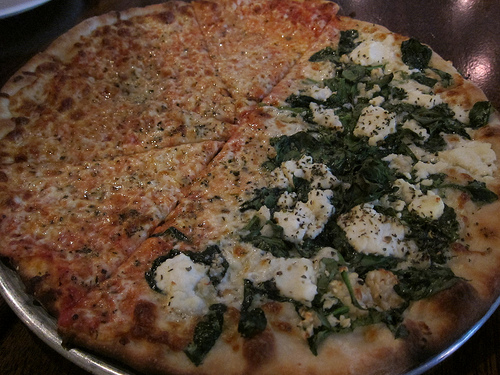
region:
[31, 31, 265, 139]
a piece of food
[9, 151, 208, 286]
a piece of food item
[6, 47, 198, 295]
a piece of pizza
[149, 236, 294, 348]
a decoration on food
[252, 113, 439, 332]
a decoration on food item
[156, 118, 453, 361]
a decoration on pizza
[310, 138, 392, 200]
green leaves on the food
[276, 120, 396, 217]
green leaves on the pizza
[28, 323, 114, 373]
a round part of plate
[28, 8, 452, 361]
a round plate with pizza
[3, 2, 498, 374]
eight slices of pizza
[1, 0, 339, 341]
four slices of plain cheese pizza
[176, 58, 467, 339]
spinach topping on pizza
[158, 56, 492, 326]
ricotta cheese topping on pizza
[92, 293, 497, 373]
part of the crust on pizza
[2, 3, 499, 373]
pizza on flat tin pan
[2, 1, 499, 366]
pizza split in half according to topping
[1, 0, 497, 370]
pizza fresh out of the oven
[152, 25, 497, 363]
cooked spinach and cheese on pizza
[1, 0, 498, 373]
melted cheese and spices on pizza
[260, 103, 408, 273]
Spinach on top of the pizza.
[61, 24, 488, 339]
Whole pizza in the pan.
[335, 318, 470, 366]
Crust of the pizza.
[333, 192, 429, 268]
White chunk of cheese on the pizza.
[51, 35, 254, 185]
The pizza is half chees.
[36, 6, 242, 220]
The cheese size cut in fours.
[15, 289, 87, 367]
The pan is silver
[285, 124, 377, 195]
The spinach is green.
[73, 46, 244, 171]
The pizza has garlic on it.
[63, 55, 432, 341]
The pizza is cooked well done.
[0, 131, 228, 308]
silce of a cheese pizza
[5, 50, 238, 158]
silce of a cheese pizza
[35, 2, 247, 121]
silce of a cheese pizza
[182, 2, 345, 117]
silce of a cheese pizza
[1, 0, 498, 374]
pizza on a metal tray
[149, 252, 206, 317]
clump of cheese on a pizza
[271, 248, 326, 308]
clump of cheese on a pizza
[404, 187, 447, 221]
clump of cheese on a pizza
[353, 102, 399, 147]
clump of cheese on a pizza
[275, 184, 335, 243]
clump of cheese on a pizza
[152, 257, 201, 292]
A crumble of Mozzarella cheese.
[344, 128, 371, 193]
Seasoned and cooked spinach.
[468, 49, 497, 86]
The reflection of an overhead light.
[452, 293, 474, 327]
Burnt pizza crust.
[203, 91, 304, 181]
Dead center of pizza pie.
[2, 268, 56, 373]
Aluminum pizza pie plate.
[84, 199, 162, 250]
Spices on a pizza pie.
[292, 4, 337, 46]
Red Roma tomatoe sauce on pizza.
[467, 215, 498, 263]
Grains of fresh cracked black pepper.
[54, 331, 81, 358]
Pizza toppings stuck to a pie pan.